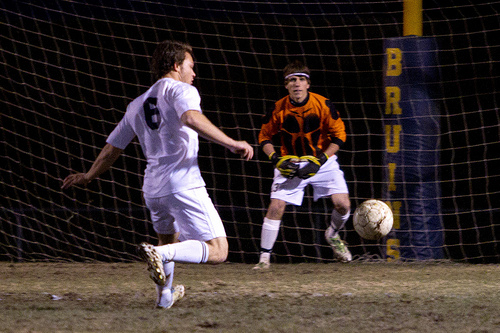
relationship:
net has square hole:
[0, 1, 492, 253] [449, 156, 473, 182]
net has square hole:
[0, 1, 492, 253] [19, 79, 89, 146]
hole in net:
[32, 211, 46, 224] [0, 1, 492, 253]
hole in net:
[421, 196, 440, 213] [330, 7, 495, 262]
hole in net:
[235, 227, 248, 243] [0, 1, 492, 253]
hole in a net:
[455, 207, 479, 231] [0, 1, 492, 253]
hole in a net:
[416, 163, 439, 183] [0, 1, 492, 253]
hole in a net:
[352, 164, 371, 184] [25, 48, 103, 111]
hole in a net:
[352, 136, 367, 153] [0, 1, 492, 253]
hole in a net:
[48, 201, 73, 221] [0, 1, 492, 253]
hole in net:
[241, 251, 257, 265] [365, 77, 470, 188]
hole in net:
[312, 229, 327, 243] [0, 1, 492, 253]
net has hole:
[0, 1, 492, 253] [273, 223, 311, 254]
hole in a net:
[227, 206, 257, 240] [0, 1, 492, 253]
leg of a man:
[248, 189, 295, 254] [251, 61, 351, 270]